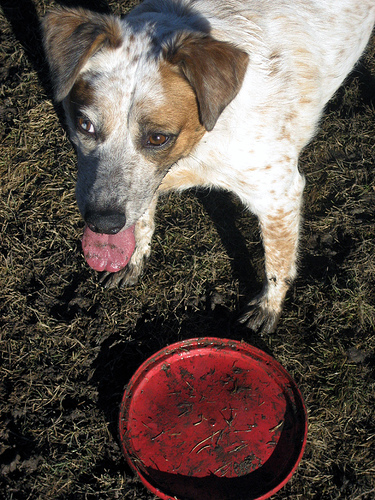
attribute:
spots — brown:
[268, 49, 320, 141]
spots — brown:
[261, 207, 296, 278]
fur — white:
[33, 0, 372, 288]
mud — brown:
[0, 0, 373, 495]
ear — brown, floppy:
[159, 22, 251, 132]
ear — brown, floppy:
[35, 4, 126, 102]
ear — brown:
[171, 34, 254, 135]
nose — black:
[81, 211, 125, 234]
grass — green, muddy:
[320, 379, 363, 451]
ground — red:
[2, 4, 370, 497]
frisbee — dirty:
[116, 332, 311, 490]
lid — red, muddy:
[122, 335, 302, 497]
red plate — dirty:
[116, 334, 307, 499]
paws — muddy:
[111, 259, 285, 333]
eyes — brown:
[75, 110, 168, 146]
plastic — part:
[158, 309, 256, 388]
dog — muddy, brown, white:
[25, 0, 373, 338]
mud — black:
[97, 322, 251, 407]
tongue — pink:
[76, 227, 140, 270]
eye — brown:
[133, 123, 184, 149]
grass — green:
[0, 1, 374, 497]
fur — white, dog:
[116, 29, 167, 108]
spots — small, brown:
[125, 35, 140, 64]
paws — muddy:
[104, 252, 277, 325]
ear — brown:
[42, 10, 110, 101]